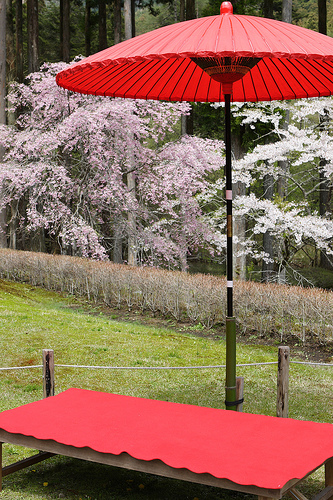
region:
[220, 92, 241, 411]
Umbrella pole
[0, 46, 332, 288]
Pink flowering trees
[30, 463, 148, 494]
Small yellow flowers under stage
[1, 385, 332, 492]
The red stage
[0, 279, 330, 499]
The grass lawn the stage is on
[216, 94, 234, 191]
Top black portion of the pole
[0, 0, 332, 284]
Tall trees in the background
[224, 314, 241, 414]
Green portion of the pole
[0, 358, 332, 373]
Rope barrier around the stage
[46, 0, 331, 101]
The red umbrella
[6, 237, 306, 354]
rows of bare bushes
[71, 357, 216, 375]
a thick, white rope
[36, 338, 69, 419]
a short wooden post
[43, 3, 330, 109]
a bright red umbrella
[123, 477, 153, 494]
a few yellow wildflowers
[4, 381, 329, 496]
a short wooden bench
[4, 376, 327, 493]
a bright red bench covering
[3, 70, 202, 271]
pale pink cherry blossoms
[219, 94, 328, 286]
tree covered in white flowers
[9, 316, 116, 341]
field of grass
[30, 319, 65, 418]
Weathered brown wooden post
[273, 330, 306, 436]
Weathered brown wooden post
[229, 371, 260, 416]
Weathered brown wooden post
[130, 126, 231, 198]
Flowers from a cherry tree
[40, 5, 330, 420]
Umbrella with red fabric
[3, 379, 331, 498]
Bench covered in red fabric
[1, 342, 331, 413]
Fence made of wood and rope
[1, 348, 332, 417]
Fence made of rope and wooden posts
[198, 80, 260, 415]
Umbrella pole made of metal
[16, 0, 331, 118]
Red umbrella canopy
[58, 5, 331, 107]
large red umbrella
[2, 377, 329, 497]
red cot on display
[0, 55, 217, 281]
pink cherry tree in bloom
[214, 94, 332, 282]
white cherry tree in bloom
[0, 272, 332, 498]
short green grass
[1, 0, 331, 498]
asian style outdoor scene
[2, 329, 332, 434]
rope fence with wood posts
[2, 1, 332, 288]
tall trees in forest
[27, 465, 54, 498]
small yellow flowers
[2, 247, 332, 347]
bush or hedge on edge of grass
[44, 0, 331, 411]
The umbrella is red.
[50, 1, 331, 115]
The umbrella is open.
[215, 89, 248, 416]
Umbrella is on a long pole.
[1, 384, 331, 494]
Platform is covered in red.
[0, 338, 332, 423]
Platform and umbrella is roped off.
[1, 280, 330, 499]
The grass is green.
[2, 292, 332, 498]
The grass is cut low.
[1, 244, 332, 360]
The bushes are brown.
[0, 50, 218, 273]
Trees have pink blossoms.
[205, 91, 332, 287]
Trees have white blossoms.